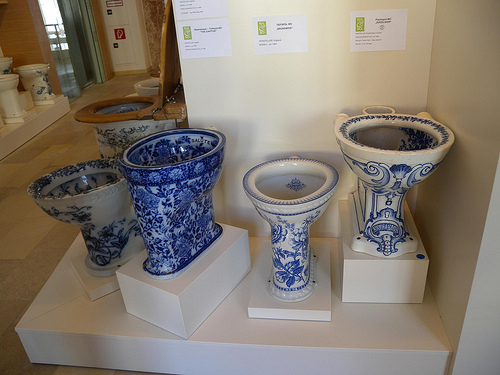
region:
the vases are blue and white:
[68, 122, 440, 326]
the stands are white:
[110, 265, 275, 372]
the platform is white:
[17, 273, 232, 373]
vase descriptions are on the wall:
[157, 7, 445, 142]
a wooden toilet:
[89, 81, 219, 170]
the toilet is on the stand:
[83, 99, 194, 196]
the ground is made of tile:
[2, 170, 114, 371]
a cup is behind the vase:
[341, 92, 451, 126]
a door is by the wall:
[77, 20, 239, 66]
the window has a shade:
[45, 42, 257, 162]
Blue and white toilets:
[34, 92, 467, 352]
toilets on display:
[21, 93, 463, 333]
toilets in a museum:
[23, 90, 468, 327]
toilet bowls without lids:
[24, 124, 348, 308]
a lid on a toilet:
[77, 13, 177, 137]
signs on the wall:
[173, 12, 430, 62]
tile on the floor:
[6, 180, 36, 297]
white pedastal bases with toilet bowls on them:
[111, 240, 443, 341]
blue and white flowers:
[125, 175, 215, 255]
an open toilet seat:
[81, 7, 169, 125]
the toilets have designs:
[36, 95, 453, 293]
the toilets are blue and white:
[35, 98, 457, 289]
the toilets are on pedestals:
[70, 241, 427, 337]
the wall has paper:
[172, 2, 407, 57]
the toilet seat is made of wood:
[74, 0, 169, 123]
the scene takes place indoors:
[0, 1, 499, 372]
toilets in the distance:
[0, 55, 47, 122]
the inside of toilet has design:
[286, 178, 306, 198]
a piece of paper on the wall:
[176, 17, 228, 59]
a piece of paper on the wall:
[344, 5, 414, 48]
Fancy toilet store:
[1, 0, 498, 372]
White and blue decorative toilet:
[330, 100, 457, 257]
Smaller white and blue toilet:
[238, 150, 339, 305]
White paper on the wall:
[347, 5, 409, 55]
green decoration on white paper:
[353, 13, 366, 33]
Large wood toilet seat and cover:
[69, 0, 182, 122]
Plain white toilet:
[2, 70, 32, 125]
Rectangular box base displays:
[113, 218, 253, 337]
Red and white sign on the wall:
[113, 23, 126, 40]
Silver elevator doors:
[50, 1, 105, 91]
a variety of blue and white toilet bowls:
[12, 11, 484, 362]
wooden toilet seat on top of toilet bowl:
[76, 0, 179, 123]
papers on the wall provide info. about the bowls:
[172, 0, 432, 68]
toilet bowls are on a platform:
[21, 98, 452, 326]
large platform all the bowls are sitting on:
[15, 225, 451, 373]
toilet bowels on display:
[0, 47, 75, 163]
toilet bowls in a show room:
[5, 0, 491, 370]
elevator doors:
[51, 0, 109, 98]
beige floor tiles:
[5, 71, 161, 366]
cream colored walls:
[173, 2, 497, 347]